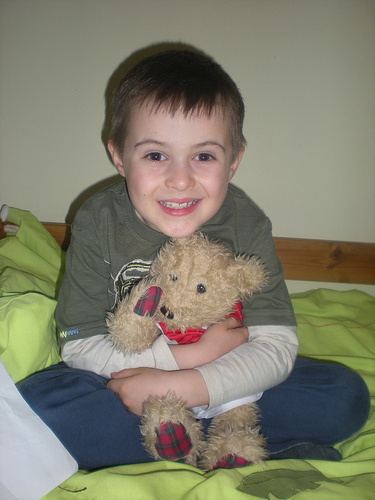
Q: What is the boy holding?
A: Teddy bear.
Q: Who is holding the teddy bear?
A: The boy.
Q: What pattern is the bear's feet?
A: Plaid.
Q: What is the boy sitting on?
A: A bed.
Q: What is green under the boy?
A: Blanket.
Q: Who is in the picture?
A: A boy.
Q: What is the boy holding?
A: A teddy bear.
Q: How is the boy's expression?
A: Smiling.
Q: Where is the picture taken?
A: A bedroom.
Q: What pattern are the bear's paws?
A: Red plaid.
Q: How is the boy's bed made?
A: Of wood.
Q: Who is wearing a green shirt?
A: A boy.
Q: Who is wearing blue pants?
A: The boy.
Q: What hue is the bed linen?
A: Green.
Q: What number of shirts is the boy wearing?
A: Two.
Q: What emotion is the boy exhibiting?
A: Happiness.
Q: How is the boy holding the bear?
A: Hugging it.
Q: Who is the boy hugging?
A: Bear.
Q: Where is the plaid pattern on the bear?
A: Paws.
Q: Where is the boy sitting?
A: On bed.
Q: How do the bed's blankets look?
A: Rumpled.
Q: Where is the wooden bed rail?
A: Behind the boy.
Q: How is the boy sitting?
A: Legs crossed.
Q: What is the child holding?
A: Teddy bear.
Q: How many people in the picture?
A: One.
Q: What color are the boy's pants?
A: Blue.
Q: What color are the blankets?
A: Green.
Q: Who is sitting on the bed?
A: A boy.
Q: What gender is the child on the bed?
A: Male.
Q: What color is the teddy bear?
A: Brown.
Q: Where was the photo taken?
A: On a bed.